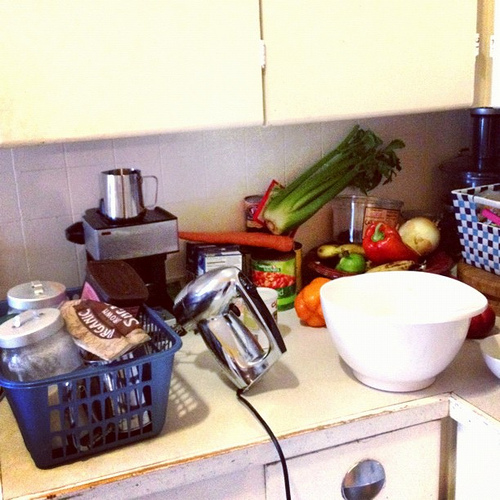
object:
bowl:
[319, 269, 490, 395]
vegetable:
[263, 123, 405, 235]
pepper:
[294, 276, 331, 328]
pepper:
[362, 221, 424, 266]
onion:
[397, 215, 441, 255]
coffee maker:
[64, 207, 182, 328]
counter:
[0, 285, 499, 499]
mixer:
[171, 266, 288, 395]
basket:
[0, 283, 185, 469]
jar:
[0, 307, 87, 450]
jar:
[6, 281, 70, 317]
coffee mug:
[100, 167, 160, 225]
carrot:
[176, 231, 296, 254]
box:
[186, 241, 245, 276]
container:
[79, 260, 150, 320]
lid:
[85, 259, 150, 302]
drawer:
[263, 419, 445, 500]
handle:
[340, 456, 387, 498]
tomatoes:
[252, 270, 294, 288]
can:
[247, 247, 296, 311]